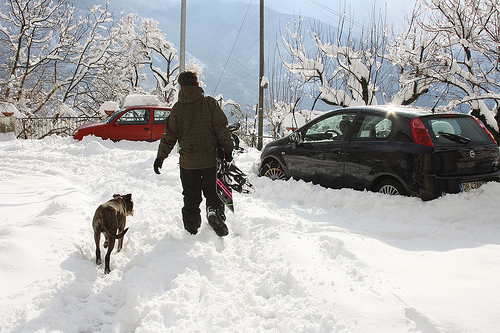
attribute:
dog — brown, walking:
[91, 181, 131, 261]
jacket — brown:
[160, 93, 231, 166]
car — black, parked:
[258, 89, 447, 190]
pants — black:
[178, 165, 226, 240]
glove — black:
[146, 155, 171, 181]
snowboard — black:
[213, 135, 262, 228]